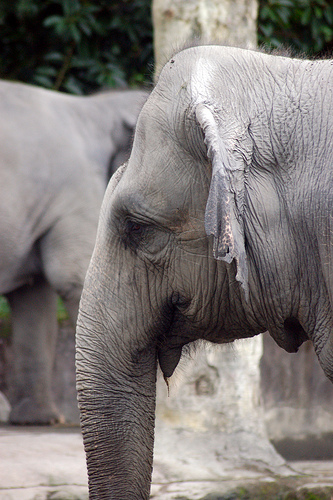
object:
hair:
[163, 23, 243, 49]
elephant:
[75, 44, 330, 500]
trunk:
[76, 251, 160, 495]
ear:
[179, 97, 248, 296]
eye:
[126, 215, 151, 235]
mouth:
[147, 295, 185, 377]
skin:
[273, 62, 328, 141]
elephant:
[1, 76, 151, 424]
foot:
[9, 385, 66, 426]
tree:
[150, 1, 298, 476]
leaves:
[323, 25, 332, 41]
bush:
[1, 0, 150, 87]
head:
[103, 44, 301, 372]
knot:
[195, 372, 216, 397]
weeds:
[209, 484, 331, 500]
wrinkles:
[193, 274, 262, 338]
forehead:
[128, 48, 192, 159]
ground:
[5, 424, 332, 500]